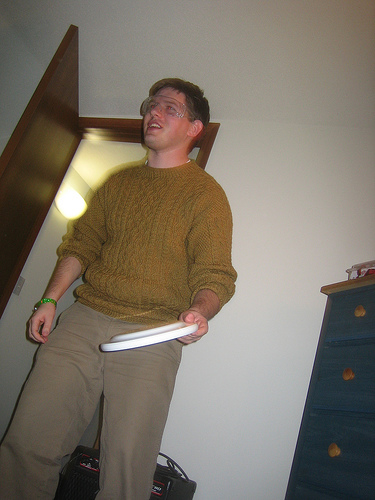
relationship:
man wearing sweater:
[3, 77, 238, 499] [58, 158, 238, 321]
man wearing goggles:
[3, 77, 238, 499] [140, 93, 198, 130]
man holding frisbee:
[3, 77, 238, 499] [99, 319, 199, 354]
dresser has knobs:
[280, 275, 373, 499] [325, 302, 367, 457]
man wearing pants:
[3, 77, 238, 499] [2, 301, 187, 499]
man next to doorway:
[3, 77, 238, 499] [1, 127, 198, 469]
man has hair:
[3, 77, 238, 499] [147, 74, 211, 158]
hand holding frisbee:
[175, 308, 209, 344] [99, 319, 199, 354]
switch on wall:
[13, 274, 26, 298] [4, 7, 373, 499]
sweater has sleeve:
[58, 158, 238, 321] [186, 180, 238, 313]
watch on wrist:
[31, 297, 58, 310] [36, 292, 59, 312]